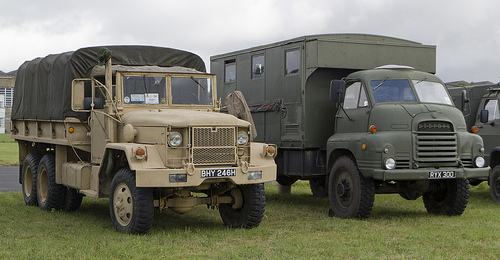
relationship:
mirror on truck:
[330, 79, 345, 104] [209, 32, 491, 218]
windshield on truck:
[122, 76, 212, 106] [10, 44, 277, 233]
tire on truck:
[109, 168, 155, 234] [10, 44, 277, 233]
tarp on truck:
[11, 44, 207, 118] [10, 44, 277, 233]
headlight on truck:
[168, 131, 184, 146] [10, 44, 277, 233]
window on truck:
[285, 47, 301, 74] [209, 32, 491, 218]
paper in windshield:
[145, 92, 159, 105] [122, 76, 212, 106]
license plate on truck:
[201, 169, 237, 177] [10, 44, 277, 233]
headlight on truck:
[237, 131, 248, 145] [10, 44, 277, 233]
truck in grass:
[10, 44, 277, 233] [3, 185, 497, 259]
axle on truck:
[153, 190, 243, 213] [10, 44, 277, 233]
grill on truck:
[192, 128, 237, 166] [10, 44, 277, 233]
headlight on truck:
[386, 157, 396, 168] [10, 44, 277, 233]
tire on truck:
[327, 154, 374, 220] [209, 32, 491, 218]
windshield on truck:
[371, 78, 453, 104] [209, 32, 491, 218]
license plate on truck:
[429, 170, 455, 178] [209, 32, 491, 218]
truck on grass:
[209, 32, 491, 218] [3, 185, 497, 259]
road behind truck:
[2, 165, 25, 192] [10, 44, 277, 233]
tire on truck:
[37, 155, 64, 210] [10, 44, 277, 233]